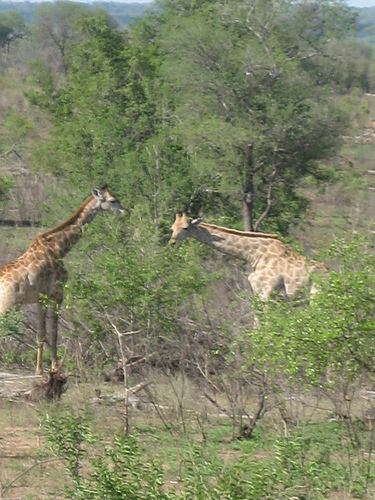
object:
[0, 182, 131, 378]
adult giraffe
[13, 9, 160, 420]
left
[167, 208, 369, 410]
adult giraffe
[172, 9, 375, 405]
right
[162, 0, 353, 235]
tree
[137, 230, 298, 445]
bush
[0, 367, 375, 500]
ground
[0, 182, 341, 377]
two giraffes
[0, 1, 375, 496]
jungle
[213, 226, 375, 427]
bush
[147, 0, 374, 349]
trees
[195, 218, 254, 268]
bent neck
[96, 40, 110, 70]
green leaves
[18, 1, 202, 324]
tree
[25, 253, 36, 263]
brown spots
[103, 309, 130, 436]
branches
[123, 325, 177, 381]
no leaves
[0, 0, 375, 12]
sky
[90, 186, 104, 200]
ear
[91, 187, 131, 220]
side of head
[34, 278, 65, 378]
two front legs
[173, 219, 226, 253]
shadow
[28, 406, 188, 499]
shrubs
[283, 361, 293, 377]
leaves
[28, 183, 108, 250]
fur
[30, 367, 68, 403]
trunk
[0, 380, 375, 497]
grass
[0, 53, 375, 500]
plains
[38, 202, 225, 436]
brush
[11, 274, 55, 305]
stomach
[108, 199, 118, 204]
eye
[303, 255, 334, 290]
front hip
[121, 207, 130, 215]
nose